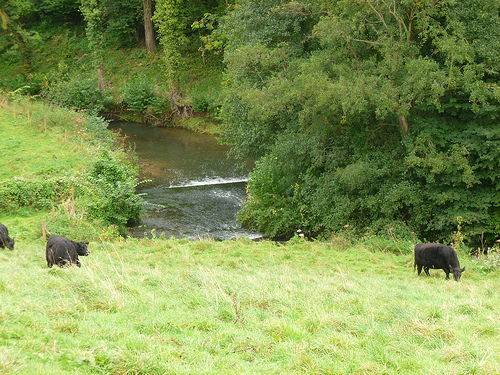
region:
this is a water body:
[153, 131, 229, 218]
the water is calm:
[146, 146, 206, 181]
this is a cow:
[411, 238, 464, 287]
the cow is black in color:
[423, 245, 443, 257]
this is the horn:
[458, 259, 467, 274]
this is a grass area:
[213, 261, 405, 368]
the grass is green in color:
[152, 286, 232, 363]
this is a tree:
[361, 38, 458, 175]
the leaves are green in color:
[316, 69, 428, 184]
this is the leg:
[413, 260, 424, 276]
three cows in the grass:
[1, 214, 478, 288]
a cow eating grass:
[406, 232, 471, 293]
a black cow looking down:
[401, 223, 473, 293]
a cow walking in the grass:
[38, 215, 92, 272]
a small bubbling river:
[93, 93, 273, 260]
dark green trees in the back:
[295, 33, 462, 215]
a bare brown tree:
[122, 0, 159, 57]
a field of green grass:
[111, 256, 386, 347]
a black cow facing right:
[407, 230, 467, 282]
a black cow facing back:
[37, 220, 88, 275]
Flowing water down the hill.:
[103, 112, 268, 239]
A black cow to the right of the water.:
[411, 239, 465, 281]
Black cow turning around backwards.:
[41, 229, 90, 270]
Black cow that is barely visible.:
[1, 220, 17, 251]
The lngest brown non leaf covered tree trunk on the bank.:
[139, 0, 156, 54]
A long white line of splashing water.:
[167, 172, 249, 189]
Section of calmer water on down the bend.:
[100, 116, 244, 172]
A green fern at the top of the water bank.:
[86, 175, 166, 236]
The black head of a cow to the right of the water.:
[448, 263, 464, 281]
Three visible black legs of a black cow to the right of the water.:
[413, 261, 451, 278]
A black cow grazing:
[399, 225, 489, 283]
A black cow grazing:
[40, 218, 97, 264]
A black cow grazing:
[0, 229, 21, 248]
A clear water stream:
[126, 100, 246, 242]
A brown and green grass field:
[260, 294, 447, 359]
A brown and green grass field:
[18, 295, 180, 369]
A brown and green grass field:
[18, 104, 107, 224]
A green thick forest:
[318, 26, 485, 266]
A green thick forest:
[218, 16, 321, 181]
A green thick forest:
[65, 0, 210, 97]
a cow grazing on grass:
[412, 246, 464, 277]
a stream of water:
[145, 140, 220, 220]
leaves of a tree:
[265, 150, 355, 206]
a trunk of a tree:
[140, 6, 150, 41]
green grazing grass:
[238, 300, 374, 350]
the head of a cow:
[452, 266, 460, 279]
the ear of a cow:
[461, 268, 469, 273]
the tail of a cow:
[413, 262, 415, 272]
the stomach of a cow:
[424, 251, 441, 266]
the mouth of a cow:
[87, 250, 91, 257]